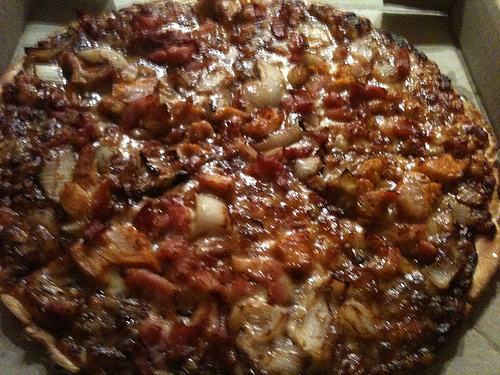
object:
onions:
[287, 277, 329, 357]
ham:
[196, 168, 236, 200]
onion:
[38, 142, 79, 201]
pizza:
[5, 6, 491, 371]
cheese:
[240, 58, 286, 105]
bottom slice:
[12, 249, 496, 372]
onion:
[34, 63, 66, 85]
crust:
[0, 0, 479, 370]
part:
[9, 155, 443, 366]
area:
[224, 278, 344, 372]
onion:
[97, 138, 130, 170]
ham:
[120, 81, 171, 133]